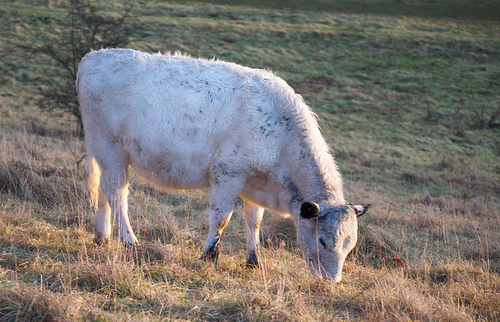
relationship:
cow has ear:
[76, 47, 370, 283] [299, 200, 322, 219]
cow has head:
[76, 47, 370, 283] [296, 199, 374, 285]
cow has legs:
[76, 47, 370, 283] [93, 159, 266, 271]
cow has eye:
[76, 47, 370, 283] [318, 236, 329, 250]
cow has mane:
[76, 47, 370, 283] [267, 75, 343, 201]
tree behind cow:
[16, 1, 158, 139] [76, 47, 370, 283]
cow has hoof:
[76, 47, 370, 283] [125, 242, 142, 250]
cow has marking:
[76, 47, 370, 283] [199, 237, 221, 265]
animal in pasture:
[76, 47, 370, 283] [1, 0, 500, 319]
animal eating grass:
[76, 47, 370, 283] [1, 0, 500, 319]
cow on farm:
[76, 47, 370, 283] [1, 0, 500, 319]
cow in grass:
[76, 47, 370, 283] [1, 0, 500, 319]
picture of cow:
[1, 1, 499, 322] [76, 47, 370, 283]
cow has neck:
[76, 47, 370, 283] [269, 125, 347, 222]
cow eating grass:
[76, 47, 370, 283] [1, 0, 500, 319]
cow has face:
[76, 47, 370, 283] [315, 234, 360, 284]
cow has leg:
[76, 47, 370, 283] [200, 165, 247, 264]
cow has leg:
[76, 47, 370, 283] [241, 197, 264, 271]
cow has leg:
[76, 47, 370, 283] [89, 149, 142, 249]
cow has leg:
[76, 47, 370, 283] [93, 189, 112, 246]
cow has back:
[76, 47, 370, 283] [81, 47, 278, 79]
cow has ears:
[76, 47, 370, 283] [299, 199, 372, 219]